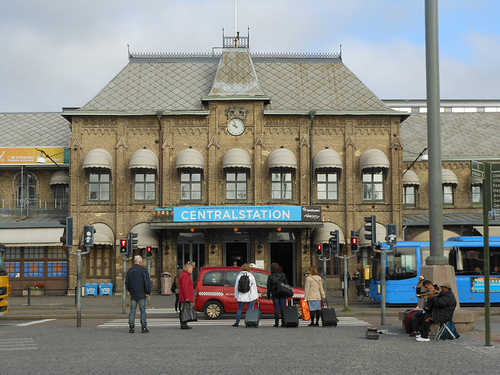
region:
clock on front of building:
[223, 117, 245, 139]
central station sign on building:
[175, 200, 305, 220]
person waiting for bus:
[172, 257, 201, 332]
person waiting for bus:
[126, 247, 152, 338]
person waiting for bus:
[261, 262, 296, 334]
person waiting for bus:
[296, 265, 340, 332]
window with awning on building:
[124, 143, 159, 207]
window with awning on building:
[76, 142, 114, 204]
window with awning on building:
[314, 145, 345, 200]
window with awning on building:
[351, 142, 389, 205]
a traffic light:
[313, 210, 387, 310]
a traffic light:
[349, 150, 443, 365]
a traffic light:
[308, 120, 422, 372]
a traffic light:
[253, 171, 441, 353]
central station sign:
[163, 189, 364, 259]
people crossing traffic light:
[54, 209, 183, 338]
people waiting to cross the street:
[117, 251, 370, 358]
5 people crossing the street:
[131, 247, 356, 340]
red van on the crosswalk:
[175, 254, 337, 327]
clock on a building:
[189, 94, 291, 167]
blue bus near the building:
[352, 202, 499, 317]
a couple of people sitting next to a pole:
[378, 248, 481, 360]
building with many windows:
[92, 97, 426, 253]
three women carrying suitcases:
[210, 241, 342, 350]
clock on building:
[216, 110, 260, 150]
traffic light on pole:
[358, 210, 395, 280]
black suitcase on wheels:
[275, 301, 301, 331]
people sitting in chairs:
[393, 268, 474, 353]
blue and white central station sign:
[158, 197, 313, 229]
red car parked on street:
[186, 265, 306, 332]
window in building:
[125, 143, 165, 208]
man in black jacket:
[113, 255, 161, 340]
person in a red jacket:
[166, 260, 205, 327]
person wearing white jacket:
[226, 257, 263, 330]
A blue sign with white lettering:
[160, 195, 317, 228]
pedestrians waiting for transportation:
[120, 248, 348, 334]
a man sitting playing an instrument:
[401, 267, 467, 348]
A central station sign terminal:
[169, 202, 314, 222]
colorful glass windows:
[7, 245, 74, 283]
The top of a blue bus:
[365, 232, 498, 280]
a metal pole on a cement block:
[417, 4, 458, 279]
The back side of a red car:
[204, 266, 234, 318]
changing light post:
[62, 216, 99, 331]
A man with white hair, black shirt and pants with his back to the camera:
[125, 250, 155, 336]